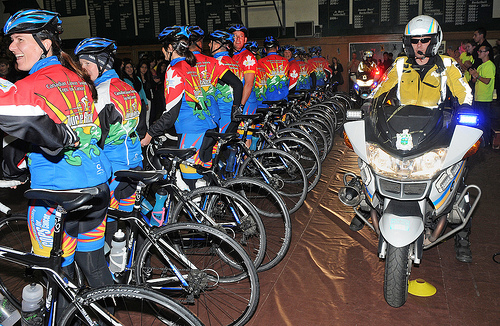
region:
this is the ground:
[280, 278, 322, 302]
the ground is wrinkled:
[307, 242, 344, 290]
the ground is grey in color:
[313, 252, 339, 287]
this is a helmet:
[406, 18, 438, 45]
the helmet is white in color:
[411, 22, 423, 35]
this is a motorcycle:
[348, 104, 485, 301]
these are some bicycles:
[41, 85, 349, 324]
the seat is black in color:
[65, 194, 79, 205]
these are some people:
[11, 4, 329, 112]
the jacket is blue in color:
[179, 118, 189, 129]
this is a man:
[369, 18, 472, 105]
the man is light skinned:
[16, 43, 32, 61]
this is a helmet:
[401, 11, 441, 35]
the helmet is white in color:
[416, 21, 434, 30]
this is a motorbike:
[346, 114, 471, 254]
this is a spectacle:
[406, 37, 434, 47]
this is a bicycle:
[35, 238, 148, 316]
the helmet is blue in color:
[81, 40, 100, 47]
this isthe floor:
[287, 258, 360, 325]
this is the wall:
[283, 9, 360, 34]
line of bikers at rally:
[6, 15, 326, 292]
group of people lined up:
[0, 9, 317, 288]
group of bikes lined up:
[0, 85, 344, 305]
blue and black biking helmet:
[0, 8, 59, 29]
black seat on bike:
[28, 184, 91, 211]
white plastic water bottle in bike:
[17, 285, 46, 308]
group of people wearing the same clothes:
[0, 5, 328, 215]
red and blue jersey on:
[25, 73, 97, 187]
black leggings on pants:
[45, 253, 104, 309]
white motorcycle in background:
[331, 97, 480, 303]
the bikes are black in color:
[93, 129, 354, 270]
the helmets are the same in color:
[16, 9, 121, 71]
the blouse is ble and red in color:
[29, 85, 100, 174]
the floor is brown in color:
[316, 241, 364, 318]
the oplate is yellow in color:
[415, 270, 435, 300]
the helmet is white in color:
[398, 17, 436, 39]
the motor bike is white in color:
[368, 122, 457, 239]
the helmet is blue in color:
[72, 28, 119, 58]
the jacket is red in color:
[385, 53, 450, 103]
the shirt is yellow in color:
[475, 57, 492, 100]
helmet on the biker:
[4, 7, 65, 34]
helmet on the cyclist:
[74, 38, 119, 50]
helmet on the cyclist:
[157, 26, 192, 37]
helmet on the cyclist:
[210, 26, 230, 41]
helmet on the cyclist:
[261, 32, 271, 42]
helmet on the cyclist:
[191, 28, 207, 36]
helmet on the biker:
[396, 16, 448, 38]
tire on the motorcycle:
[374, 245, 426, 308]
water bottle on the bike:
[109, 227, 130, 272]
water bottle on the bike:
[21, 278, 44, 315]